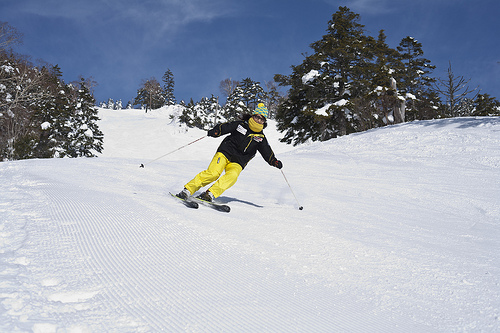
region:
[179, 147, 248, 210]
bright yellow ski pants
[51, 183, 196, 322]
some stripes in the snow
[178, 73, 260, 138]
a few snow covered trees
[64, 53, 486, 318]
a bluebird day on the slopes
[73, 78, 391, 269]
a woman downhill skiing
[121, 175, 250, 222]
a pair of skiis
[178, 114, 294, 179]
a black ski jacket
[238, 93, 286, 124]
a green and yellow hat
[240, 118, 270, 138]
a neon yellow scarf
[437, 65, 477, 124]
a bare tree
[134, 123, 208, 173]
Pole is used by downhill skier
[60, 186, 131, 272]
Texture in the snow left by a snow vehicle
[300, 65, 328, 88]
Clumps of snow sitting in a tree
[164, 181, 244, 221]
Skis used by downhill skier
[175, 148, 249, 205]
Yellow snow pants worn by downhill skier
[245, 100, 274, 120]
Toboggan cap worn by skier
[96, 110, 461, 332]
Downhill slope of a ski hill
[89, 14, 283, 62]
Deep blue winter sky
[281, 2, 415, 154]
Evergreen trees in the snow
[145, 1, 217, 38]
White clouds in the deep blue sky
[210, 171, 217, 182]
the pants is yellow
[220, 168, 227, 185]
the pants is yellow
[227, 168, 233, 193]
the pants is yellow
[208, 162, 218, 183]
the pants is yellow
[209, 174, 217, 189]
the pants is yellow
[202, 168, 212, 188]
the pants is yellow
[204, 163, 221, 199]
the pants is yellow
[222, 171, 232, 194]
the pants is yellow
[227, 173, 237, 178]
the pants is yellow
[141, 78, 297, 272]
skier skiing down the slope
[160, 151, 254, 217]
ski pants are yellow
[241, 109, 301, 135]
scarf is yellow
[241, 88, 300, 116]
hat is checkered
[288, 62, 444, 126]
snow on the tree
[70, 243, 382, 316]
snow on the ground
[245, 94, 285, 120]
hat is green and yellow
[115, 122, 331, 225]
skiier using ski poles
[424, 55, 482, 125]
tree doesn't have leaves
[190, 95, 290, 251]
skiier leaning towards the left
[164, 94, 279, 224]
a women skies down the mountain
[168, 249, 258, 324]
lines in the snow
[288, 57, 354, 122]
snow covered trees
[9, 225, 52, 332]
a pile of snow on the track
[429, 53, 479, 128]
a tree bare of leaves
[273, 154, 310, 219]
a pole on the ground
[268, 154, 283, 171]
the hand holding the pole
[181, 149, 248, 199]
the yellow pants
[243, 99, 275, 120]
a green and yellow beanie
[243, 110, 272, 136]
a yellow scarf on her mouth